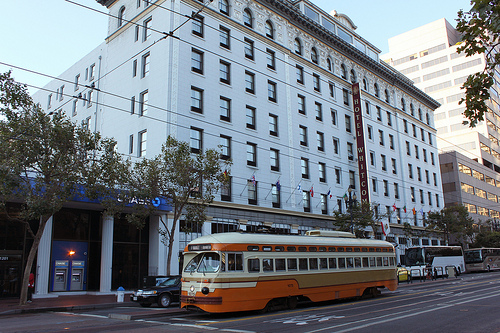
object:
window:
[218, 94, 232, 124]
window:
[267, 111, 279, 135]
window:
[243, 142, 257, 167]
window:
[269, 185, 283, 209]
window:
[264, 50, 277, 70]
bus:
[397, 244, 467, 279]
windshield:
[180, 252, 224, 272]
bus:
[180, 230, 400, 314]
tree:
[130, 134, 235, 302]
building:
[0, 173, 182, 299]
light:
[64, 247, 76, 255]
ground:
[344, 148, 397, 204]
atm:
[69, 260, 85, 290]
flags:
[208, 157, 449, 224]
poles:
[212, 162, 445, 222]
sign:
[350, 82, 373, 218]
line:
[57, 309, 255, 332]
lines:
[217, 271, 497, 332]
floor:
[0, 289, 499, 332]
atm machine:
[50, 257, 68, 292]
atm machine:
[70, 259, 85, 293]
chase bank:
[0, 174, 169, 300]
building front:
[174, 0, 442, 273]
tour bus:
[397, 243, 466, 279]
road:
[1, 265, 498, 332]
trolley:
[178, 225, 400, 317]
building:
[14, 1, 448, 283]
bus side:
[223, 242, 400, 316]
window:
[183, 251, 218, 274]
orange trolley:
[178, 229, 398, 317]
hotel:
[24, 0, 447, 289]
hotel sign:
[351, 77, 372, 216]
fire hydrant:
[116, 285, 126, 304]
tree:
[0, 68, 112, 317]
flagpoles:
[263, 174, 283, 204]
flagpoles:
[315, 187, 333, 212]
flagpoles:
[206, 165, 232, 195]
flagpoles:
[283, 176, 303, 203]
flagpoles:
[387, 202, 397, 221]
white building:
[2, 0, 445, 285]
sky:
[14, 16, 87, 47]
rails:
[398, 242, 463, 280]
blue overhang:
[0, 172, 175, 213]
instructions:
[267, 312, 349, 325]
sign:
[150, 195, 163, 208]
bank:
[0, 171, 182, 298]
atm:
[53, 259, 69, 290]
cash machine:
[51, 259, 70, 291]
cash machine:
[69, 258, 85, 291]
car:
[129, 272, 184, 308]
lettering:
[348, 83, 370, 213]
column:
[100, 210, 116, 291]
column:
[32, 205, 51, 300]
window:
[241, 4, 253, 27]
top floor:
[0, 0, 499, 122]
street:
[0, 269, 499, 332]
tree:
[0, 74, 108, 306]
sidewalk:
[1, 289, 134, 314]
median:
[397, 264, 459, 284]